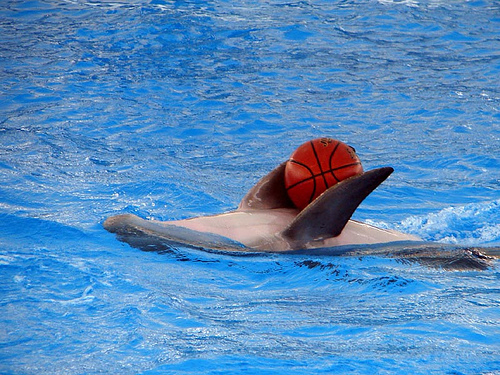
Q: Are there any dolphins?
A: Yes, there is a dolphin.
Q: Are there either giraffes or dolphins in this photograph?
A: Yes, there is a dolphin.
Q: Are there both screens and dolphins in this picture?
A: No, there is a dolphin but no screens.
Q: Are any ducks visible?
A: No, there are no ducks.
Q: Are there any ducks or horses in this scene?
A: No, there are no ducks or horses.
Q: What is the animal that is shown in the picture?
A: The animal is a dolphin.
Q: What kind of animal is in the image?
A: The animal is a dolphin.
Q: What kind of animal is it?
A: The animal is a dolphin.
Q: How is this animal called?
A: This is a dolphin.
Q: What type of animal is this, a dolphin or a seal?
A: This is a dolphin.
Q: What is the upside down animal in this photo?
A: The animal is a dolphin.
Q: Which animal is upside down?
A: The animal is a dolphin.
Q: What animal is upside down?
A: The animal is a dolphin.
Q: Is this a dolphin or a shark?
A: This is a dolphin.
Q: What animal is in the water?
A: The dolphin is in the water.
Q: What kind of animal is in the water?
A: The animal is a dolphin.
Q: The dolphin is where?
A: The dolphin is in the water.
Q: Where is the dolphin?
A: The dolphin is in the water.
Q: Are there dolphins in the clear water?
A: Yes, there is a dolphin in the water.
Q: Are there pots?
A: No, there are no pots.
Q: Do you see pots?
A: No, there are no pots.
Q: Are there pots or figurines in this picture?
A: No, there are no pots or figurines.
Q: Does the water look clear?
A: Yes, the water is clear.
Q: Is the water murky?
A: No, the water is clear.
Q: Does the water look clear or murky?
A: The water is clear.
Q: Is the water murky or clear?
A: The water is clear.